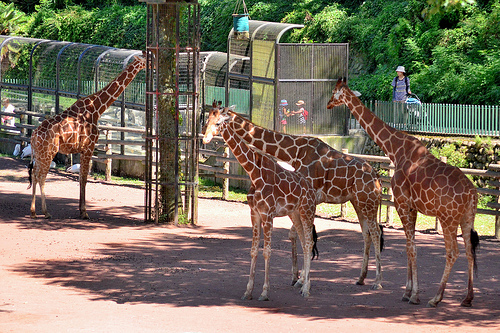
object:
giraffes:
[198, 99, 318, 272]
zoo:
[0, 57, 499, 333]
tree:
[157, 13, 181, 225]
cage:
[140, 1, 202, 225]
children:
[274, 96, 293, 134]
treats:
[285, 108, 297, 121]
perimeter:
[328, 123, 499, 143]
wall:
[361, 138, 500, 177]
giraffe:
[324, 77, 481, 289]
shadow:
[140, 236, 218, 296]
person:
[387, 63, 413, 108]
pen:
[9, 39, 64, 112]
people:
[388, 64, 413, 129]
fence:
[98, 126, 144, 164]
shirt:
[392, 78, 406, 100]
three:
[197, 77, 485, 308]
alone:
[22, 54, 151, 220]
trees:
[33, 0, 140, 40]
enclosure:
[0, 32, 170, 114]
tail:
[27, 137, 34, 191]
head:
[324, 78, 352, 111]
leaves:
[323, 13, 332, 33]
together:
[204, 76, 481, 250]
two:
[274, 91, 310, 136]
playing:
[274, 95, 307, 119]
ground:
[0, 227, 238, 333]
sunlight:
[61, 118, 82, 142]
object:
[230, 1, 252, 42]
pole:
[188, 4, 202, 224]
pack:
[302, 109, 307, 120]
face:
[200, 111, 225, 148]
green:
[95, 17, 111, 29]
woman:
[390, 66, 415, 102]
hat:
[395, 63, 405, 73]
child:
[409, 105, 420, 118]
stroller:
[404, 122, 424, 132]